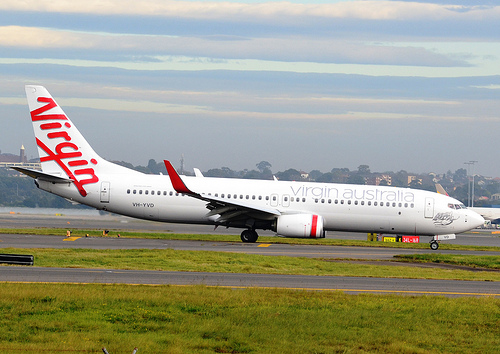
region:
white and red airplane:
[7, 67, 485, 254]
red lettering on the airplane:
[32, 92, 94, 202]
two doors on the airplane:
[94, 181, 439, 225]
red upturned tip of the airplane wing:
[162, 159, 184, 194]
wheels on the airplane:
[233, 224, 440, 248]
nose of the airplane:
[471, 208, 485, 231]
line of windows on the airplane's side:
[122, 184, 418, 211]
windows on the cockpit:
[448, 197, 468, 212]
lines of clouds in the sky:
[6, 4, 493, 161]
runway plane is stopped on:
[7, 224, 489, 261]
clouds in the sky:
[28, 10, 493, 86]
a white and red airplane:
[6, 85, 491, 247]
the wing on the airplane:
[160, 156, 266, 226]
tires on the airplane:
[240, 226, 256, 243]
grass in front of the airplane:
[15, 237, 496, 272]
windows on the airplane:
[125, 186, 415, 206]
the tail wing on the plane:
[25, 80, 100, 186]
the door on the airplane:
[420, 195, 435, 221]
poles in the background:
[456, 152, 486, 207]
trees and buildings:
[236, 165, 486, 183]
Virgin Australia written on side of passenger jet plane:
[287, 183, 414, 203]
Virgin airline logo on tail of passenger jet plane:
[26, 96, 98, 196]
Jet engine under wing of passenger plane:
[275, 215, 322, 237]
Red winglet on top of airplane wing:
[162, 158, 194, 194]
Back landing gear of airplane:
[239, 228, 259, 243]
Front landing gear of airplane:
[430, 239, 437, 249]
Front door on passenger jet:
[424, 196, 434, 220]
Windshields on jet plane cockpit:
[446, 201, 468, 212]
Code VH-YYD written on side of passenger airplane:
[130, 200, 157, 210]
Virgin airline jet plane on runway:
[10, 83, 487, 254]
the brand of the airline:
[283, 181, 416, 207]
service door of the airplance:
[425, 196, 437, 216]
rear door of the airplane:
[100, 180, 111, 201]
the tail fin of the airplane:
[22, 80, 110, 167]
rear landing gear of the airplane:
[239, 227, 261, 244]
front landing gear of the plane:
[429, 235, 440, 251]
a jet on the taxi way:
[7, 83, 484, 250]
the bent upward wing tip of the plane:
[161, 158, 186, 194]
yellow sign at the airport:
[383, 235, 396, 245]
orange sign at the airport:
[400, 232, 418, 243]